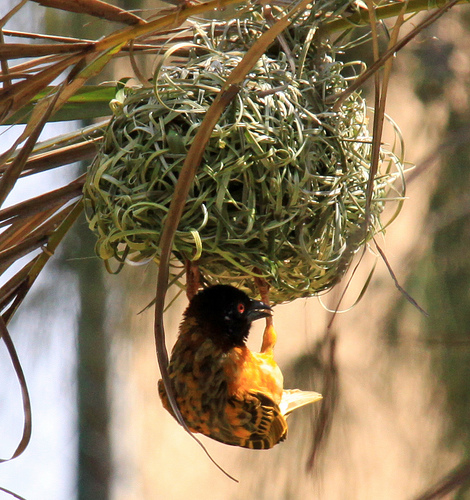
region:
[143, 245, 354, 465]
A bird hangs from its nest.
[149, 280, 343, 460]
The bird is yellow and black.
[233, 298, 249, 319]
The bird's eye is red.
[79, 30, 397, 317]
The nest is made of grass.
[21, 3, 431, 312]
The nest hangs from branches.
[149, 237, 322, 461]
The bird is underneath the nest.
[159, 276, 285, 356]
The bird's head is black.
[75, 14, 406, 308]
The nest is green.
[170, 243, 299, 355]
The bird's legs grip the nest.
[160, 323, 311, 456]
The bird's feathers are speckled.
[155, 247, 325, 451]
bird hanging upside down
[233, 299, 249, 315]
red and black eye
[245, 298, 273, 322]
beak on birds face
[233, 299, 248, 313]
eye on birds face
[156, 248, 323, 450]
black and yellow bird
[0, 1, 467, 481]
branch from unknown tree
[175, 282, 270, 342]
head of bird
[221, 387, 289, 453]
black and yellow bird wing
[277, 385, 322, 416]
yellow tail on bird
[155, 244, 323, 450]
bird with open beak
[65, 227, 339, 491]
an exotic colorful bird hanging from a ball in a tree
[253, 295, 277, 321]
the black pointed beak of the bird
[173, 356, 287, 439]
a yellow and black speckled body of the bird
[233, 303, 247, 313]
a red glassy eye of the bird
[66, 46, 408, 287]
a green ball of thin plant leaves in a tree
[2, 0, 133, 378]
leaves of a palm tree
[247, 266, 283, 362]
the led of the bird holding on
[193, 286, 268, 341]
the fuzzy black head of the bird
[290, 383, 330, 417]
the yellow tail feathers of the bird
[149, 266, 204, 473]
a long dry brown leaf hanging down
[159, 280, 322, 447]
yellow black and green small bird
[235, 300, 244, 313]
round red and black bird eye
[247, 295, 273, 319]
pointy small bird beak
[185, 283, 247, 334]
small feathered black head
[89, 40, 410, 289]
green nest of clumped grass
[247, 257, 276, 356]
yellow skinny bird leg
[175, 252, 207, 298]
yellow skinny bird leg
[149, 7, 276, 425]
long narrow dry palm leaf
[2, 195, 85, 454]
long narrow dry palm leaf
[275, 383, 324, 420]
wide yellow feathered tail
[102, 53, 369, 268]
a round bird's nest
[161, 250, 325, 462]
a bird hanging from a nest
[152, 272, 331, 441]
a yellow and black bird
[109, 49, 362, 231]
a bird's nest that looks like it is made of rubber bands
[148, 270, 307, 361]
a bird's head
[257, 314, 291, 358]
a bird's leg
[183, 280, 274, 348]
a bird's head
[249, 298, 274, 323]
a bird's beak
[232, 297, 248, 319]
a bird's eye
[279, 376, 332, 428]
a bird's tail feathers